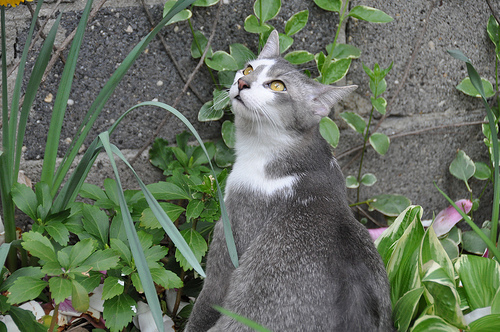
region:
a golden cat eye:
[265, 80, 286, 93]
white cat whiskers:
[246, 99, 284, 139]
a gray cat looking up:
[178, 30, 397, 329]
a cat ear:
[313, 79, 364, 115]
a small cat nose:
[236, 77, 249, 90]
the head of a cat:
[223, 26, 355, 134]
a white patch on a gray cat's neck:
[213, 118, 299, 206]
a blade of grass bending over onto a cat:
[109, 102, 240, 270]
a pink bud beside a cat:
[428, 195, 475, 236]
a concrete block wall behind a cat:
[1, 1, 498, 221]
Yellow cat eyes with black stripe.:
[224, 48, 322, 103]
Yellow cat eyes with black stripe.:
[235, 89, 245, 103]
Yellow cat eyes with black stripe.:
[391, 216, 413, 251]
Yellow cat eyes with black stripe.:
[15, 275, 115, 326]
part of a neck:
[220, 120, 300, 254]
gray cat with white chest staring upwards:
[178, 24, 403, 329]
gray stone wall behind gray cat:
[7, 0, 499, 307]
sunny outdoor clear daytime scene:
[5, 6, 493, 328]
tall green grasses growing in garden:
[12, 0, 237, 331]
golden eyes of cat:
[236, 58, 288, 95]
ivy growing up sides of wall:
[158, 0, 498, 305]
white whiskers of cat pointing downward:
[206, 80, 281, 142]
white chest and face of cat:
[213, 58, 309, 198]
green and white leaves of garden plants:
[379, 204, 499, 330]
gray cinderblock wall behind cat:
[7, 4, 497, 276]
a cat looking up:
[151, 35, 398, 330]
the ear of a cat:
[310, 72, 360, 115]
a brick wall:
[40, 24, 170, 144]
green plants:
[17, 155, 207, 273]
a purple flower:
[380, 178, 484, 240]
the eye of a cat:
[260, 74, 292, 99]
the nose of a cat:
[233, 76, 253, 91]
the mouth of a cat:
[228, 91, 254, 111]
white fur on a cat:
[227, 147, 294, 194]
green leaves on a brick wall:
[442, 48, 498, 113]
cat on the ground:
[183, 23, 471, 330]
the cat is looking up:
[125, 28, 467, 328]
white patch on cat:
[225, 50, 298, 195]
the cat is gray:
[205, 125, 386, 330]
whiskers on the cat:
[193, 60, 303, 142]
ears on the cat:
[243, 23, 375, 133]